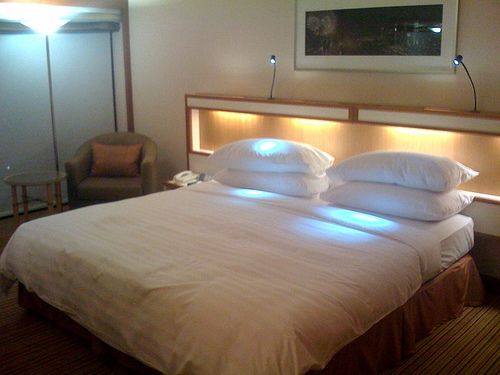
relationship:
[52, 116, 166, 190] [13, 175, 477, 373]
chair next to bed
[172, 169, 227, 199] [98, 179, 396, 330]
telephone next to bed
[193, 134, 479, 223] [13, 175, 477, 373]
pillow stacked on bed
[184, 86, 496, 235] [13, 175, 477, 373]
headboard of bed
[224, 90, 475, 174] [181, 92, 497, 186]
lights in headboard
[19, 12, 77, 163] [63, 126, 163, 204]
light above chair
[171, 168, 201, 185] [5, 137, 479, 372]
telephone next to bed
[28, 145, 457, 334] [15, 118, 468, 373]
comforter on a bed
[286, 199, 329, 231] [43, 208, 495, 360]
sheet on a bed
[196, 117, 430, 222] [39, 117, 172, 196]
pillow in chair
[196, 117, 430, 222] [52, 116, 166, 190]
pillow in chair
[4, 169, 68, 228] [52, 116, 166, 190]
table to chair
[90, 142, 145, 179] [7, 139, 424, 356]
pillow on a bed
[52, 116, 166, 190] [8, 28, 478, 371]
chair of a room